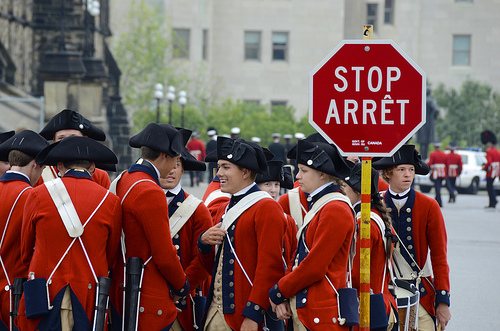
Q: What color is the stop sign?
A: Red and White.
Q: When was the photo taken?
A: Daytime.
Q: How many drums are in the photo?
A: One.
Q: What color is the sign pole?
A: Yellow and Orange.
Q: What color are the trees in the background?
A: Green.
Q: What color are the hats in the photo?
A: Black.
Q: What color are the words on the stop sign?
A: White.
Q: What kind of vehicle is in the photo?
A: A car.